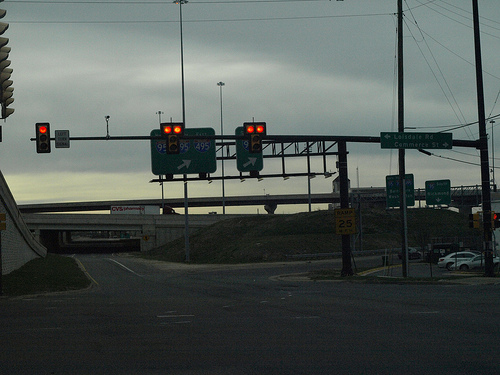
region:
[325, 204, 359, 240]
yellow and black sign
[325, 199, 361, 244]
25 m.p.h speed sign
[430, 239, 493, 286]
cars in a paking lot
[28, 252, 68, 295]
patch of green grass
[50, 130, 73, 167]
small black and white sign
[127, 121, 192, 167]
a double red light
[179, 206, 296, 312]
hill on a road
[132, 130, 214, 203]
green white and blue sign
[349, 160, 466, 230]
double sign on highway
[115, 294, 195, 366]
white lines on road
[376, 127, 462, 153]
a green street sign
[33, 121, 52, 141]
a red traffic light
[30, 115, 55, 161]
a bank of traffic lights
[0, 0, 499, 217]
gray clouds in the sky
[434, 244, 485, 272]
a white car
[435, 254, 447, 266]
the tail light of a car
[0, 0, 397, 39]
a wire in the sky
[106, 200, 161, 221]
the trailer of a truck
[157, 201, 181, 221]
the cab of a truck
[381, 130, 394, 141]
an arrow on the sign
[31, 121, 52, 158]
this is a traffic light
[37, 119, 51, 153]
the traffic light indicates red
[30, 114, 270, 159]
they are three traffic lights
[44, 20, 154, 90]
this is the sky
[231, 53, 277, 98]
these are the clouds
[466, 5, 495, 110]
this is a pole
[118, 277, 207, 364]
this is a road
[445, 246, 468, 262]
this is a car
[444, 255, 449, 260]
the car is white in color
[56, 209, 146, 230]
this is a flyover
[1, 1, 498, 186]
The sky is cloudy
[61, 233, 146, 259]
Bridge is casting a shadow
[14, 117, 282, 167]
Three traffic lights in the foreground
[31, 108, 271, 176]
Traffic lights are on red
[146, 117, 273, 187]
Highway signs are green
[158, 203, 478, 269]
A hill of grass is in the background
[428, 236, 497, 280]
Two cars are in the background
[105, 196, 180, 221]
A truck is on the highway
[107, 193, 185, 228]
The back of the truck is white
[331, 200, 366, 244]
Yellow sign says the number 25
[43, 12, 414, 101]
The weather is bad.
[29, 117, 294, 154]
The street light is red.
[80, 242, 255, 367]
The road is baren.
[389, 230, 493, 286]
There are a few cars on the side.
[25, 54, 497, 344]
It looks like a bad weather day.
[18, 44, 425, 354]
It must be early in the morning.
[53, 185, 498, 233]
There is a large highway above the road.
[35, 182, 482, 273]
The highway is dead.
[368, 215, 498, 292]
The several cars are parked.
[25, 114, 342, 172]
The street lights are pointless.